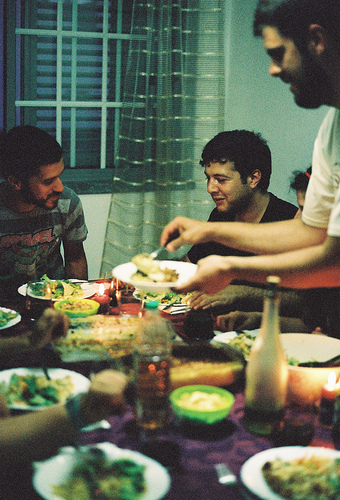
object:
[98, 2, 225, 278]
curtain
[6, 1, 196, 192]
window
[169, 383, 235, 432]
bowl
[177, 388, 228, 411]
food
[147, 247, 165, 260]
utensil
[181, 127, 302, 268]
man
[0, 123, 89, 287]
man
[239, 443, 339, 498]
plate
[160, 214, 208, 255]
hand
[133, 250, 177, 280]
food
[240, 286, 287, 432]
drink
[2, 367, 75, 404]
food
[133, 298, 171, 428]
drink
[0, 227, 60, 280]
logo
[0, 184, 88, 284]
shirt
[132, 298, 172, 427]
plastic bottle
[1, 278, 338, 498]
dinner table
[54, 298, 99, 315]
bowl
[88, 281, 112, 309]
candle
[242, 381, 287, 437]
wine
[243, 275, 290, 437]
bottle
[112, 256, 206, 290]
plate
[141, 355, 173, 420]
liquid